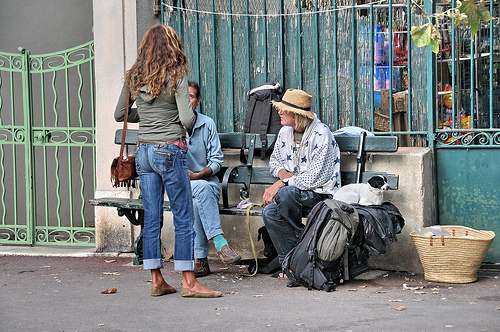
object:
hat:
[268, 87, 321, 121]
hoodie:
[111, 66, 198, 146]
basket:
[405, 219, 497, 284]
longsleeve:
[287, 139, 336, 195]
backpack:
[237, 77, 289, 162]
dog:
[331, 170, 395, 208]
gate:
[1, 24, 100, 254]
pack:
[278, 197, 360, 294]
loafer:
[214, 244, 244, 265]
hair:
[118, 23, 192, 101]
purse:
[108, 68, 139, 190]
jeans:
[131, 139, 199, 272]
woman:
[105, 20, 225, 304]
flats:
[180, 285, 223, 299]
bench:
[86, 127, 404, 283]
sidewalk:
[2, 254, 498, 332]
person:
[258, 84, 347, 279]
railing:
[148, 0, 500, 153]